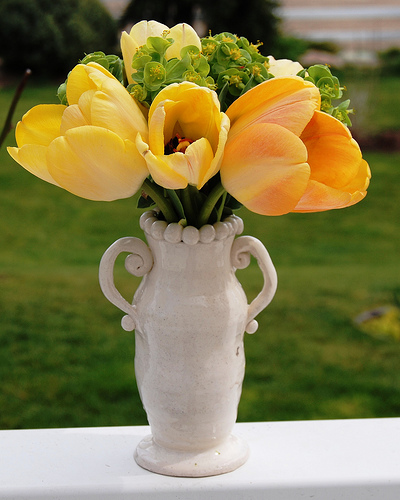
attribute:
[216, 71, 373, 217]
flower — yellow  , large 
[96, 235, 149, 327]
handle — small 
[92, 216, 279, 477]
vase — white 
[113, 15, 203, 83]
yellow flower — Yellow 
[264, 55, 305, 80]
yellow flower — Yellow 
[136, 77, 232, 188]
yellow flower — Yellow 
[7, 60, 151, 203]
yellow flower — Yellow 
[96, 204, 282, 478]
white vase — white 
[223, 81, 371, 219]
yellow flower — Yellow 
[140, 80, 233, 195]
flower — yellow , small 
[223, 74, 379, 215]
flower — small , yellow  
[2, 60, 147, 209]
flower — small , yellow  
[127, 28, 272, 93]
flowers — Green 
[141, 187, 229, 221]
green stems — Green 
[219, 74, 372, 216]
tulip — Yellow 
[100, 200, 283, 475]
vase — white 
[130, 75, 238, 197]
tulip — open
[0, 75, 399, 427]
grass — green 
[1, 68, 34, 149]
twig — brown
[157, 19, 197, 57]
flower — yellow 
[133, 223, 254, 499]
vase — white 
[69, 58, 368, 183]
tulips — open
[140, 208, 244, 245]
balls — white 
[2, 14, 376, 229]
tulips — yellow